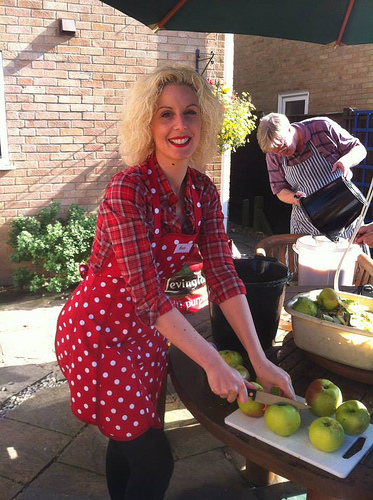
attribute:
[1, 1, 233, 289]
brick — red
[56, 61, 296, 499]
woman — blonde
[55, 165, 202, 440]
apron — red, white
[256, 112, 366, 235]
man — blonde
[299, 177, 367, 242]
bucket — black, small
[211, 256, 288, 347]
trash can — black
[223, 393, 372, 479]
cutting board — white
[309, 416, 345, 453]
apple — green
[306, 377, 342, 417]
apple — green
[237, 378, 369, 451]
apples — green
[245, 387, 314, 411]
knife — large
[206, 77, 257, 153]
plant — yellow, hanging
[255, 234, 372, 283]
chair — brown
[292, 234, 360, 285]
bucket — white